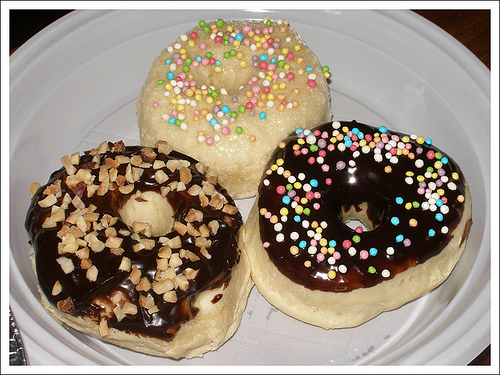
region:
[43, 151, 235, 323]
a chocolate covered donut with nuts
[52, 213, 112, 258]
chopped peanuts on chocolate icing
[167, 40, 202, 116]
colorful pastel sprinkles on a glazed donut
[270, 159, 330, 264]
colorful pastel sprinkles on chocolate icing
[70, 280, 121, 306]
smeared chocolate frosting on a donut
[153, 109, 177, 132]
beige caramel glaze on a donut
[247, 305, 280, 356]
criss cross pattern on the bottom of a bowl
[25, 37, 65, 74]
the lined edge of a white bowl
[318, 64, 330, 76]
a yellow and green sprinkle stuck together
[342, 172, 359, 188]
the light reflecting on the frosting of a donut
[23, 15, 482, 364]
three donuts sitting on a plate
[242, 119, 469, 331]
donut with chocolate frosting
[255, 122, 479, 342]
chocolate frosted donut with colorful sprinkles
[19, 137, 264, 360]
chocolate frosted donut with nuts on top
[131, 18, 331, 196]
donut with colorful sprinkles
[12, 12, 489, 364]
white plate holding donuts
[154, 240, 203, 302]
nuts on top of donut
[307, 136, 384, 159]
colorful sprinkles on donut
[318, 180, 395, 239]
hole in center of donut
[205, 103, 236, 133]
colorful sprinkles on donut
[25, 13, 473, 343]
these are donuts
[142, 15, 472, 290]
these donuts have sprinkles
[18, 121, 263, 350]
this donut has nuts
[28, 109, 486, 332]
these donuts are chocolaty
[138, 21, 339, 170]
this donut is glazed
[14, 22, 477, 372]
this plate is white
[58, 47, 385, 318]
these donuts were fried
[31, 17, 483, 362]
there are three donuts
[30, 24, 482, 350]
homemade donuts with a secret recipe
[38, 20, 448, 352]
these donuts are tan and brown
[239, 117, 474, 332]
a donut on the plate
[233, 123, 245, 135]
a green sprinkle on the donut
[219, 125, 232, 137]
a pink sprinkle on the donut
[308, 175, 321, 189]
a blue sprinkle on the donut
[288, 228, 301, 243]
a white sprinkle on the donut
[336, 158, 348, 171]
a purple sprinkle on the donut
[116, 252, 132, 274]
a chopped nut on the donut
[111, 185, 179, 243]
the middle of a donut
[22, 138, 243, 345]
brown icing on the donut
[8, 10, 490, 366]
a white plate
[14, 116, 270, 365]
donut with walnuts on top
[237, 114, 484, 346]
donut with sprinkles on top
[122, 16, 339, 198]
donut with sprinkles on top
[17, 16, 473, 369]
three donuts on a plate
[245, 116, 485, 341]
donut with chocolate on top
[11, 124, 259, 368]
donut with chocolate on top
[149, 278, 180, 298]
small chunk of walnut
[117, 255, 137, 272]
small chunk of walnut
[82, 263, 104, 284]
small chunk of walnut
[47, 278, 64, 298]
small chunk of walnut